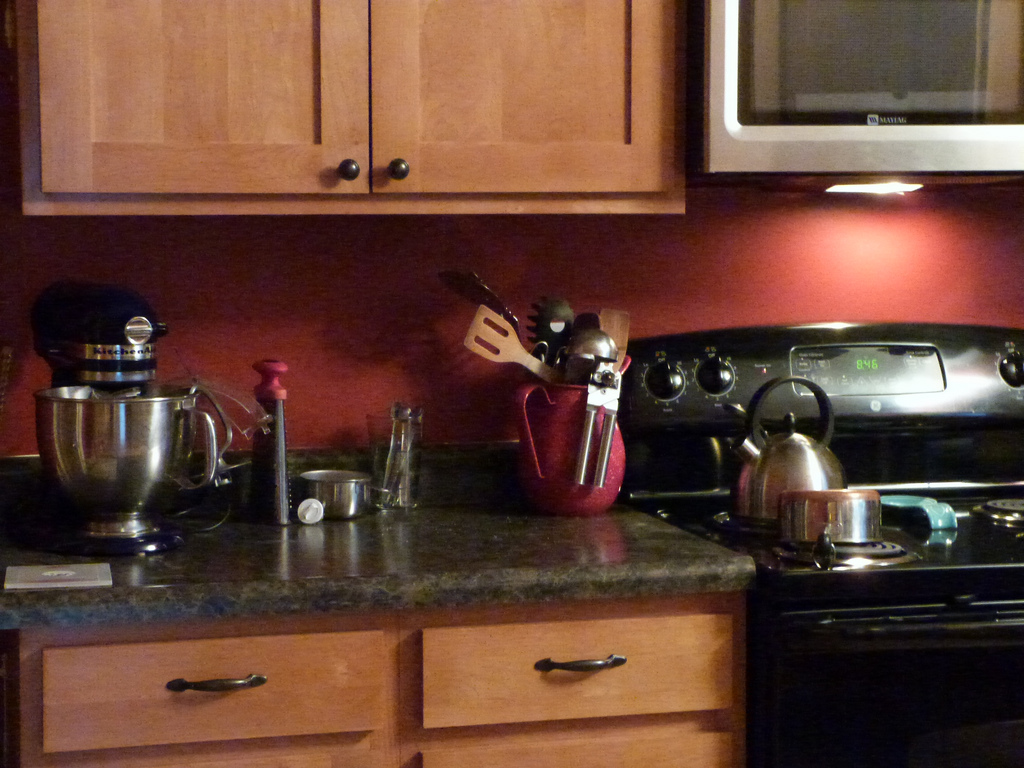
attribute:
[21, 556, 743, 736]
cabinets — wooden, brown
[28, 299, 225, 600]
mixer — silver, blue, dark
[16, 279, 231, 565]
mixer — standing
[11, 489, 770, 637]
counter — measuring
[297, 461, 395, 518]
cup — metal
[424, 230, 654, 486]
utensils — cooking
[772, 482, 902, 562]
pan — small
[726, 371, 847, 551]
kettle — tea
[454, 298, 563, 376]
spatula — wooden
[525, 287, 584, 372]
server — spaghetti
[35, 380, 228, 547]
bowl — silver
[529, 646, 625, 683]
handle — black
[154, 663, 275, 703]
handle — black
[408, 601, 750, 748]
drawer — wooden, brown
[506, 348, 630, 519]
jar — pink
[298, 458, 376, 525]
bowl — silver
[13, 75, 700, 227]
cabinet — brown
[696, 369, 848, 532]
kettle — silver, tea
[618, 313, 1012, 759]
stove — black, electric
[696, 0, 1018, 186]
microwave — stainless steel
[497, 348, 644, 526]
container — red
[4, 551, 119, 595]
case — dvd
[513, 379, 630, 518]
jug — red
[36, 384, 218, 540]
bowl — silver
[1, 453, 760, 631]
counter top — dark, granite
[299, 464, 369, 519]
bowl — silver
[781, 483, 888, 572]
saucepan — silver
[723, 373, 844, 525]
tea kettle — silver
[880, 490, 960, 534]
dish — blue, spoon rest